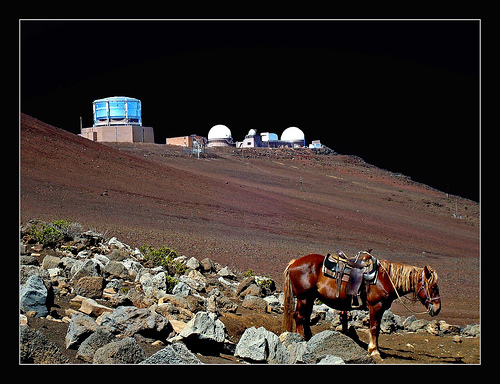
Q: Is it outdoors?
A: Yes, it is outdoors.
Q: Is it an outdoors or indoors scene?
A: It is outdoors.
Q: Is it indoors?
A: No, it is outdoors.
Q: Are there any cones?
A: No, there are no cones.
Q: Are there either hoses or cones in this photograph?
A: No, there are no cones or hoses.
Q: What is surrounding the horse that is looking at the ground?
A: The rock is surrounding the horse.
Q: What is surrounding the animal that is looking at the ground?
A: The rock is surrounding the horse.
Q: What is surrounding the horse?
A: The rock is surrounding the horse.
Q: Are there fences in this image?
A: No, there are no fences.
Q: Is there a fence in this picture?
A: No, there are no fences.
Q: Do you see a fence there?
A: No, there are no fences.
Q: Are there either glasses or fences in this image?
A: No, there are no fences or glasses.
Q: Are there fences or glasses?
A: No, there are no fences or glasses.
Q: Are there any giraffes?
A: No, there are no giraffes.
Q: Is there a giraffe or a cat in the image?
A: No, there are no giraffes or cats.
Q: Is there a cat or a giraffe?
A: No, there are no giraffes or cats.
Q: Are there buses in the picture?
A: No, there are no buses.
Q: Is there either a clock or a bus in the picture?
A: No, there are no buses or clocks.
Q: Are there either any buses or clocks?
A: No, there are no buses or clocks.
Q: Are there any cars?
A: No, there are no cars.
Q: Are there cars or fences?
A: No, there are no cars or fences.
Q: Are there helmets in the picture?
A: No, there are no helmets.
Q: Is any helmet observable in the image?
A: No, there are no helmets.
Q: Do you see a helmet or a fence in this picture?
A: No, there are no helmets or fences.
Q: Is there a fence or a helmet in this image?
A: No, there are no helmets or fences.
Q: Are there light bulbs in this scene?
A: No, there are no light bulbs.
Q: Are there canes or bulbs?
A: No, there are no bulbs or canes.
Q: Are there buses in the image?
A: No, there are no buses.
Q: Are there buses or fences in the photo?
A: No, there are no buses or fences.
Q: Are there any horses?
A: Yes, there is a horse.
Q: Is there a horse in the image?
A: Yes, there is a horse.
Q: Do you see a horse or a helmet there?
A: Yes, there is a horse.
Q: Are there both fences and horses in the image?
A: No, there is a horse but no fences.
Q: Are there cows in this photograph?
A: No, there are no cows.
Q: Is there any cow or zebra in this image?
A: No, there are no cows or zebras.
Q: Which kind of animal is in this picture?
A: The animal is a horse.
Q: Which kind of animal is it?
A: The animal is a horse.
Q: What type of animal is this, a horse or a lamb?
A: This is a horse.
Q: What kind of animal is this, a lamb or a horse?
A: This is a horse.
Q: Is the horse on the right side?
A: Yes, the horse is on the right of the image.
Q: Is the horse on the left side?
A: No, the horse is on the right of the image.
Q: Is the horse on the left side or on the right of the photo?
A: The horse is on the right of the image.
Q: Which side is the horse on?
A: The horse is on the right of the image.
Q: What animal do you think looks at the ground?
A: The horse looks at the ground.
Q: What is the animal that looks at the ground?
A: The animal is a horse.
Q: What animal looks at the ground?
A: The animal is a horse.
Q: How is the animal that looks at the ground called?
A: The animal is a horse.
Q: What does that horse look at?
A: The horse looks at the ground.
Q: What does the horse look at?
A: The horse looks at the ground.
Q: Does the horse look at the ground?
A: Yes, the horse looks at the ground.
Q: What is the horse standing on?
A: The horse is standing on the rocks.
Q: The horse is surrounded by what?
A: The horse is surrounded by the rock.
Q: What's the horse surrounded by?
A: The horse is surrounded by the rock.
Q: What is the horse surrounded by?
A: The horse is surrounded by the rock.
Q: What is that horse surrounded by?
A: The horse is surrounded by the rock.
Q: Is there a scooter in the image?
A: No, there are no scooters.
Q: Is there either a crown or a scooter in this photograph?
A: No, there are no scooters or crowns.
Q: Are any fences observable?
A: No, there are no fences.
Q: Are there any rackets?
A: No, there are no rackets.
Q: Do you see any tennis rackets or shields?
A: No, there are no tennis rackets or shields.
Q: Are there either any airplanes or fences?
A: No, there are no fences or airplanes.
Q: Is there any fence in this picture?
A: No, there are no fences.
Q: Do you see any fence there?
A: No, there are no fences.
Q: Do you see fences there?
A: No, there are no fences.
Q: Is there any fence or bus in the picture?
A: No, there are no fences or buses.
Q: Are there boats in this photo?
A: No, there are no boats.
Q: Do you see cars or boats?
A: No, there are no boats or cars.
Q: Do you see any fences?
A: No, there are no fences.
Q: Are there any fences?
A: No, there are no fences.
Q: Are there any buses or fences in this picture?
A: No, there are no fences or buses.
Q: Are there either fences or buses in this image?
A: No, there are no fences or buses.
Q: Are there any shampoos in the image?
A: No, there are no shampoos.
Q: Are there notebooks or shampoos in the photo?
A: No, there are no shampoos or notebooks.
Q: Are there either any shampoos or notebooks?
A: No, there are no shampoos or notebooks.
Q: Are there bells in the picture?
A: No, there are no bells.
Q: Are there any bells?
A: No, there are no bells.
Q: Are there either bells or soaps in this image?
A: No, there are no bells or soaps.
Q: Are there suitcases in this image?
A: No, there are no suitcases.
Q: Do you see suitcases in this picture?
A: No, there are no suitcases.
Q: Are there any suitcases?
A: No, there are no suitcases.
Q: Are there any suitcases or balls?
A: No, there are no suitcases or balls.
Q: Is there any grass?
A: Yes, there is grass.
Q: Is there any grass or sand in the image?
A: Yes, there is grass.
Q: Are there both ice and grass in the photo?
A: No, there is grass but no ice.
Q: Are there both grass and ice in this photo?
A: No, there is grass but no ice.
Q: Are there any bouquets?
A: No, there are no bouquets.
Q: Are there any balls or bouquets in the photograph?
A: No, there are no bouquets or balls.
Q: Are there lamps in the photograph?
A: No, there are no lamps.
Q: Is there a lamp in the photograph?
A: No, there are no lamps.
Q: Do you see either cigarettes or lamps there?
A: No, there are no lamps or cigarettes.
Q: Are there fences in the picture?
A: No, there are no fences.